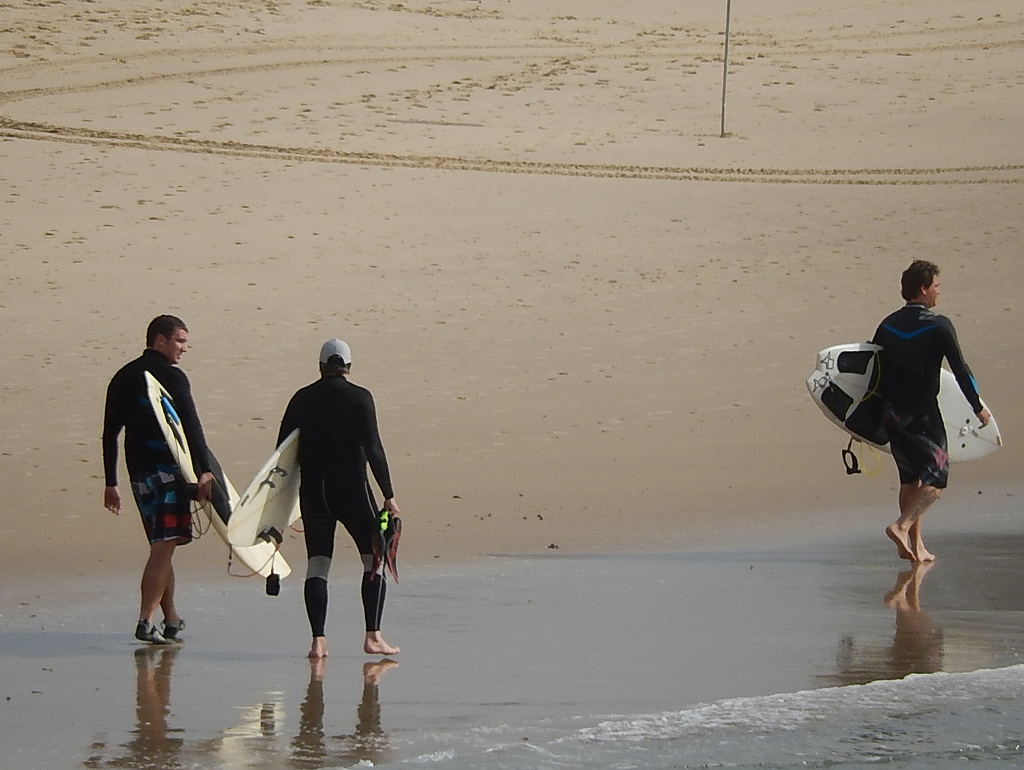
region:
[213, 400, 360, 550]
Man holding a board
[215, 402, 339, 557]
Man is holding a board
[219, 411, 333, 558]
Man holding a white board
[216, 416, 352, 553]
Man is holding a white board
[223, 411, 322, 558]
Man is holding a white surfboard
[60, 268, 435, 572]
two people holding surfboards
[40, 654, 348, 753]
reflection on the ground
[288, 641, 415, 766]
reflection of the legs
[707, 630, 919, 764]
water hitting the shore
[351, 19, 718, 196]
footprints on the sand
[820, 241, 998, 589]
man walking on the beach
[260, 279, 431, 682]
a man walking on the beach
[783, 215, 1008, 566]
a man wearing a wetsuit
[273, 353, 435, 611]
a man wearing a wetsuit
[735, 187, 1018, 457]
a man walking on the beach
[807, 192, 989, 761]
a man wearing a wetsuit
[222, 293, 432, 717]
a man wearing a wetsuit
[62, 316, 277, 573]
a man wearing a wetsuit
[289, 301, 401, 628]
a man holding a surfboard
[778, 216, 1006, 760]
a man holding a surfboard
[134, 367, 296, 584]
surfboard carried by human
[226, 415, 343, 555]
surfboard carried by human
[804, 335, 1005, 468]
surfboard carried by human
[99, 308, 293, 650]
human carries surfboard across sand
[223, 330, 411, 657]
human carries surfboard across sand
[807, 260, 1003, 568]
human carries surfboard across sand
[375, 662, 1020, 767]
wave breaks on shore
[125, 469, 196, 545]
shorts worn by human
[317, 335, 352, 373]
hat worn by human